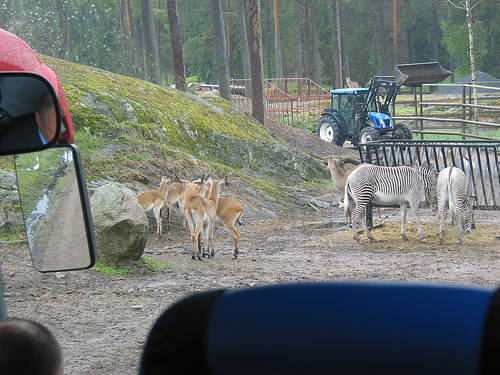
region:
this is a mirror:
[22, 147, 106, 287]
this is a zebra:
[351, 167, 423, 246]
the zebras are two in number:
[343, 167, 478, 233]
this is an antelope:
[184, 190, 216, 244]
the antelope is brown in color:
[221, 201, 233, 208]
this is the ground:
[257, 225, 306, 270]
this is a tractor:
[331, 87, 379, 137]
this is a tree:
[449, 17, 481, 60]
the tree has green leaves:
[449, 31, 463, 58]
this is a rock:
[101, 187, 133, 257]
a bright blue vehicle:
[312, 72, 434, 154]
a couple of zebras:
[318, 123, 487, 248]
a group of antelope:
[125, 164, 294, 266]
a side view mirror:
[3, 137, 110, 278]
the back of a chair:
[140, 255, 493, 352]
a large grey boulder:
[87, 158, 182, 290]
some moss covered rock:
[83, 62, 277, 170]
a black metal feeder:
[351, 125, 493, 208]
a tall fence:
[393, 78, 499, 143]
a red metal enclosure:
[213, 62, 337, 137]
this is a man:
[35, 104, 56, 131]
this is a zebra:
[356, 162, 416, 232]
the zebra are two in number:
[356, 156, 466, 228]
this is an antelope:
[191, 198, 212, 230]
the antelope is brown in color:
[222, 198, 234, 213]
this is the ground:
[73, 283, 127, 365]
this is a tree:
[449, 7, 494, 92]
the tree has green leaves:
[448, 34, 459, 53]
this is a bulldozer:
[322, 75, 399, 141]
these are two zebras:
[351, 161, 478, 230]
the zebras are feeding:
[357, 169, 472, 241]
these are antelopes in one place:
[160, 169, 244, 249]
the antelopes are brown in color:
[182, 195, 233, 222]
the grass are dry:
[470, 227, 491, 241]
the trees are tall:
[174, 17, 262, 87]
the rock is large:
[96, 182, 141, 260]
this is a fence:
[436, 140, 491, 161]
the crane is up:
[390, 54, 455, 91]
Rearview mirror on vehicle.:
[10, 141, 100, 278]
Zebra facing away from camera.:
[339, 166, 474, 246]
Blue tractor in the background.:
[317, 60, 462, 150]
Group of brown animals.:
[138, 171, 265, 260]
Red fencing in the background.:
[228, 68, 339, 129]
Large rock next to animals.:
[89, 176, 154, 263]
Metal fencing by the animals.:
[288, 86, 498, 158]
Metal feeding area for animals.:
[358, 138, 498, 208]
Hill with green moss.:
[1, 41, 348, 243]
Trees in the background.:
[3, 3, 495, 130]